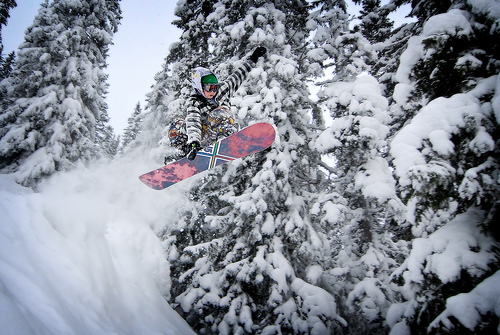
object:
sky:
[123, 7, 165, 61]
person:
[164, 46, 266, 161]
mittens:
[250, 46, 267, 65]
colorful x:
[197, 139, 235, 169]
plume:
[70, 172, 139, 230]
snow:
[49, 290, 144, 325]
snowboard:
[138, 123, 276, 191]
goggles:
[201, 84, 219, 92]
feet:
[165, 145, 204, 165]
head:
[196, 73, 220, 99]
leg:
[168, 118, 187, 150]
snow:
[0, 0, 500, 335]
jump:
[127, 108, 307, 208]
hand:
[186, 143, 204, 161]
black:
[180, 55, 257, 148]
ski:
[201, 78, 235, 120]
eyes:
[205, 87, 217, 90]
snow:
[21, 258, 420, 328]